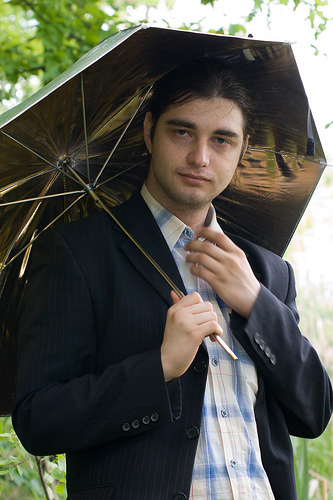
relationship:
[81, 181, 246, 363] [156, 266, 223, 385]
umbrella handle in hand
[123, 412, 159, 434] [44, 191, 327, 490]
buttons on the jacket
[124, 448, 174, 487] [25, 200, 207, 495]
pin stripes on the jacket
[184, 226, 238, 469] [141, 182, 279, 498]
buttons on the shirt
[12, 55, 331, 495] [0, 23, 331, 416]
man under an umbrella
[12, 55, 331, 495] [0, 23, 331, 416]
man is holding umbrella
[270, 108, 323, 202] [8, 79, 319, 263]
reflection in the umbrella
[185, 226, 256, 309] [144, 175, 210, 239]
hand touching neck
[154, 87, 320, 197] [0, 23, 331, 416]
shadow casting off umbrella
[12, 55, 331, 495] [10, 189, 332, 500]
man wearing jacket